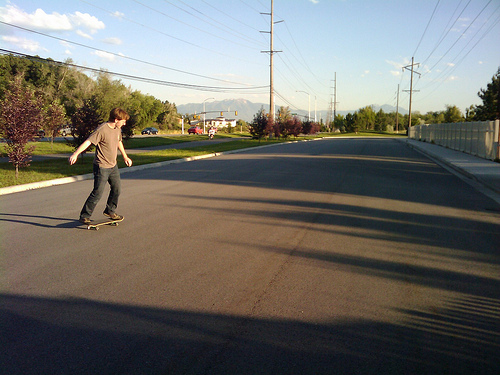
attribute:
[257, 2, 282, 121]
pole — wooden, tall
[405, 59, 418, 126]
pole — wooden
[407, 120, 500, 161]
fence — wooden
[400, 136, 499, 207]
sidewalk — cement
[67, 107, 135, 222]
man — skating, standing, young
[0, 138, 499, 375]
street — empty, smooth, paved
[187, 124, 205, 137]
car — red, driving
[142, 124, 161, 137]
car — black, blue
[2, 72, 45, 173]
tree — purple, fall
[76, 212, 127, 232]
skateboard — black, wooden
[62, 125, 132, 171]
arms — spread, extended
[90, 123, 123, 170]
shirt — brown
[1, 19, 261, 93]
wires — electric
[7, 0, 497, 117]
sky — blue, cloudy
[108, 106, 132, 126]
hair — brown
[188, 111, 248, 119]
signals — hanging